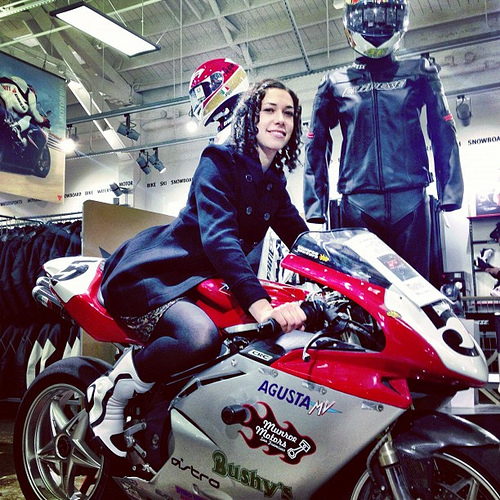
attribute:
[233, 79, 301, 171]
hair — woman's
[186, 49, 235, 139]
helmet — red, shiny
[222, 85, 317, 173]
hair — black, curly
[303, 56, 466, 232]
motorcycle jacket — black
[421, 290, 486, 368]
5 — number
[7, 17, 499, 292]
wall — white, part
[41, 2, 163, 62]
light fixture — long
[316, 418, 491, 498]
tire — large, black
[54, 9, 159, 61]
fixture — light, hanging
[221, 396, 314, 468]
sign — Agusta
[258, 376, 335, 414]
sign — Agusta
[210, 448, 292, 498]
sign — Agusta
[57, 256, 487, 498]
motorcycle — red, white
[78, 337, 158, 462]
boot — black, white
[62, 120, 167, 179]
light — in photo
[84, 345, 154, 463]
boot — white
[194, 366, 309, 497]
side — Bushy's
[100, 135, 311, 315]
coat —  black 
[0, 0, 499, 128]
ceiling — part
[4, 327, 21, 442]
jackets — black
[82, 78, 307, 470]
woman — curly, black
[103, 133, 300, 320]
jacket — long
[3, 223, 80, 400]
coats — in background